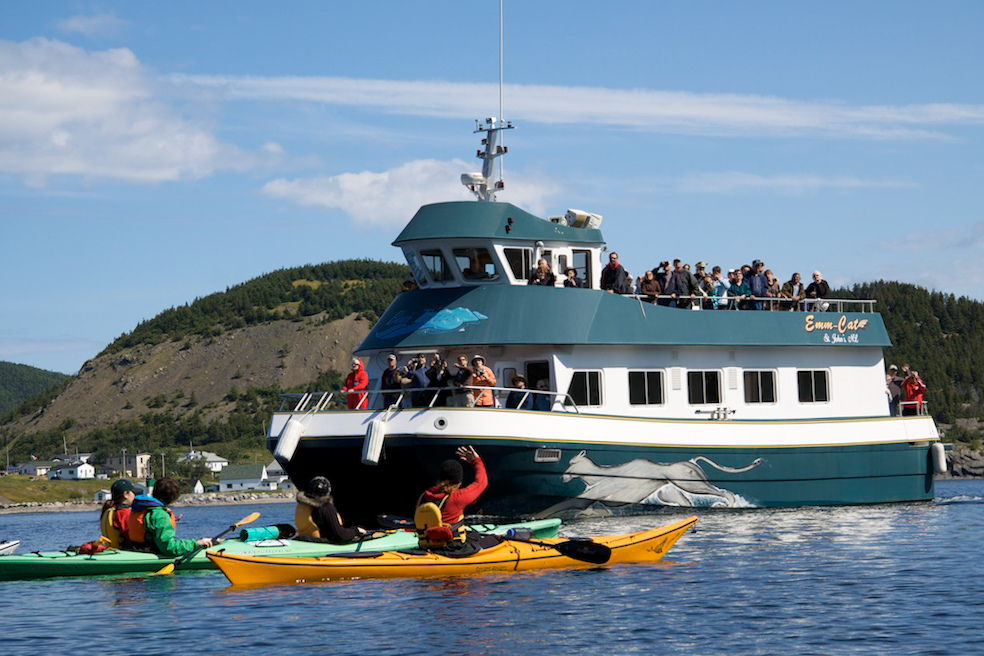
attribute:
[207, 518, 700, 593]
kayak — yellow, orange, green, black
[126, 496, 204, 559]
jacket — black, green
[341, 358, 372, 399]
coat — red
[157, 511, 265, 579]
oar — black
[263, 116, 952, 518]
ship — blue, white, floating, green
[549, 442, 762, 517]
animal — white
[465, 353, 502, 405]
person — standing, waving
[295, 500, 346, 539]
lifejacket — yellow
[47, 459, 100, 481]
house — white